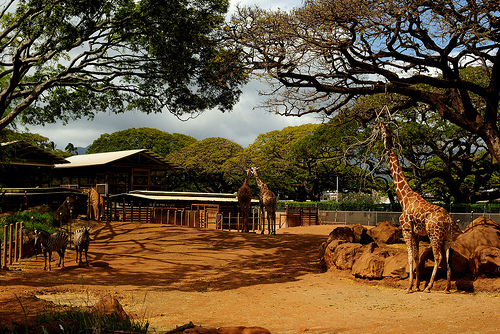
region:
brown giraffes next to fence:
[236, 161, 297, 221]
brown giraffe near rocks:
[375, 96, 455, 286]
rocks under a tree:
[325, 205, 385, 280]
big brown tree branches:
[230, 0, 425, 100]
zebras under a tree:
[35, 206, 110, 256]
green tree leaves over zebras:
[42, 2, 252, 117]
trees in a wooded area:
[185, 117, 275, 172]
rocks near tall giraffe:
[325, 205, 390, 240]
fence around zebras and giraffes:
[320, 201, 385, 211]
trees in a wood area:
[113, 120, 219, 141]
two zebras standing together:
[27, 214, 115, 269]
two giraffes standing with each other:
[231, 156, 292, 256]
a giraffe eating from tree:
[370, 97, 472, 302]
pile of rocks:
[276, 212, 387, 287]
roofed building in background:
[45, 137, 195, 219]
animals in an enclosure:
[10, 145, 485, 295]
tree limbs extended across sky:
[320, 0, 485, 110]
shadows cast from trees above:
[80, 205, 335, 280]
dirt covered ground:
[100, 220, 445, 330]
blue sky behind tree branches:
[335, 0, 490, 55]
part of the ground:
[284, 285, 299, 311]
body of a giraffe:
[430, 231, 434, 241]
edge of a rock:
[353, 241, 373, 266]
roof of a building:
[109, 149, 121, 157]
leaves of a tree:
[286, 145, 306, 162]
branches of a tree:
[301, 162, 306, 170]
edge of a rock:
[358, 246, 364, 252]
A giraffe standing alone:
[376, 124, 460, 284]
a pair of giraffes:
[235, 157, 282, 232]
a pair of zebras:
[24, 220, 101, 263]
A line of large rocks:
[331, 213, 491, 290]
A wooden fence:
[0, 214, 27, 266]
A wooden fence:
[133, 205, 282, 230]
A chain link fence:
[316, 208, 499, 232]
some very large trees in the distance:
[119, 122, 399, 205]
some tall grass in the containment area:
[21, 292, 123, 332]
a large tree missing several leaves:
[239, 0, 492, 160]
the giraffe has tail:
[338, 108, 486, 323]